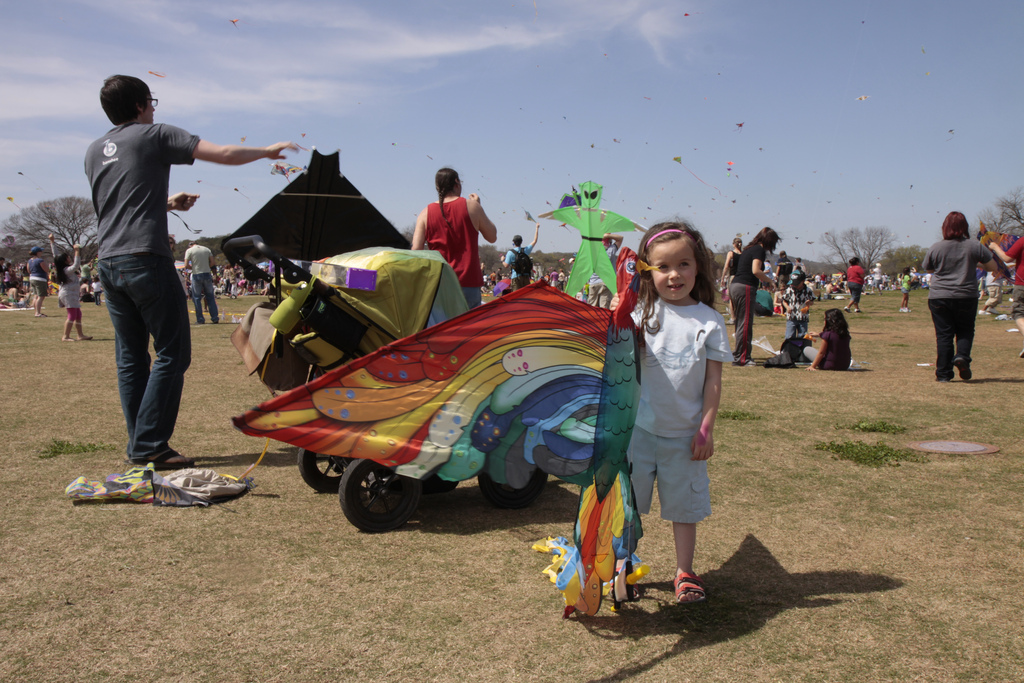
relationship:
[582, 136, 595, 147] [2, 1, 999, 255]
kite in sky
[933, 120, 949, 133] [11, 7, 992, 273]
kite in sky